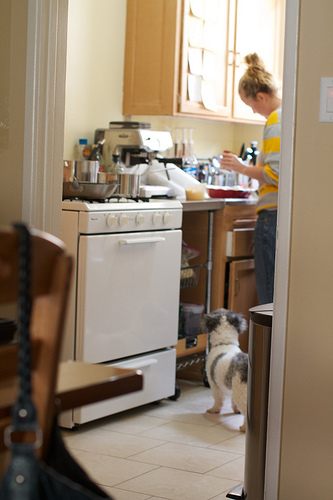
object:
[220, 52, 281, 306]
woman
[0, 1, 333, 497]
kitchen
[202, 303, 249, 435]
dog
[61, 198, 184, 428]
stove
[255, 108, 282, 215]
top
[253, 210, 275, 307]
pants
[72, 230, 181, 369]
door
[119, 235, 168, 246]
handle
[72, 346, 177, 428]
drawer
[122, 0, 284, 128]
cabinets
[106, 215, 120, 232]
knobs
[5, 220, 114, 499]
purse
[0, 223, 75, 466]
chair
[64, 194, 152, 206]
burners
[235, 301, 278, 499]
trash can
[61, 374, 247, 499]
floor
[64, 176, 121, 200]
frying pan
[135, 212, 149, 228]
knob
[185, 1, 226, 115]
sticky notes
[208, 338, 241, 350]
collar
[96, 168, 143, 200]
pot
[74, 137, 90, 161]
bottle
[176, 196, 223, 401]
rack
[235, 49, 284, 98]
hair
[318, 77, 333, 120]
light switch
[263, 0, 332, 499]
wall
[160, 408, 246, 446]
shadow